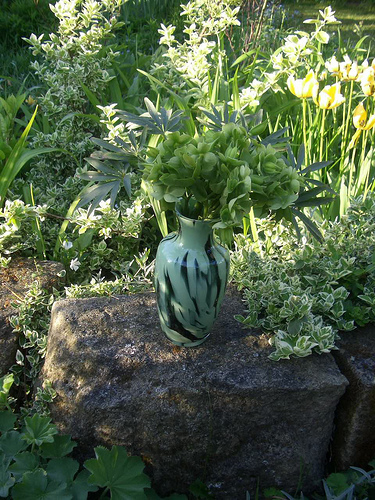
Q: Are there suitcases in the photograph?
A: No, there are no suitcases.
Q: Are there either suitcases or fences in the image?
A: No, there are no suitcases or fences.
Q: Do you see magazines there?
A: No, there are no magazines.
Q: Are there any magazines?
A: No, there are no magazines.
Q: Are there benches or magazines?
A: No, there are no magazines or benches.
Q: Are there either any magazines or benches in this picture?
A: No, there are no magazines or benches.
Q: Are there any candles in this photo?
A: No, there are no candles.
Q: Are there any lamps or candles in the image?
A: No, there are no candles or lamps.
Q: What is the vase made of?
A: The vase is made of glass.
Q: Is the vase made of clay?
A: No, the vase is made of glass.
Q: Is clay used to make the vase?
A: No, the vase is made of glass.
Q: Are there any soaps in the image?
A: No, there are no soaps.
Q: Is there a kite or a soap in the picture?
A: No, there are no soaps or kites.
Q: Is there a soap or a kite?
A: No, there are no soaps or kites.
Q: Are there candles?
A: No, there are no candles.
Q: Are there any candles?
A: No, there are no candles.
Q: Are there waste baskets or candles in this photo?
A: No, there are no candles or waste baskets.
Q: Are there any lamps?
A: No, there are no lamps.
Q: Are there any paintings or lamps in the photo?
A: No, there are no lamps or paintings.